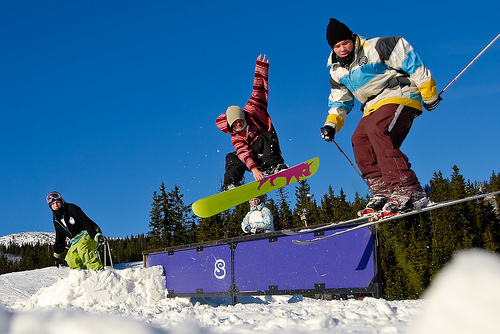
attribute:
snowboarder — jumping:
[194, 53, 323, 219]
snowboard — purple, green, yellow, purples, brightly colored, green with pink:
[189, 157, 321, 222]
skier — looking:
[43, 187, 108, 269]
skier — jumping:
[272, 15, 493, 250]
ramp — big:
[28, 261, 176, 307]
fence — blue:
[138, 215, 383, 306]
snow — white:
[3, 259, 499, 331]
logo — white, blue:
[212, 254, 230, 284]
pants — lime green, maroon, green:
[60, 228, 105, 271]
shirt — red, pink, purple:
[217, 55, 269, 171]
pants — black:
[221, 134, 286, 180]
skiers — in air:
[189, 17, 495, 245]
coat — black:
[46, 201, 102, 247]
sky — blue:
[1, 1, 492, 235]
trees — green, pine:
[3, 179, 497, 297]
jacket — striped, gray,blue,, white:
[323, 35, 441, 123]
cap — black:
[323, 14, 356, 52]